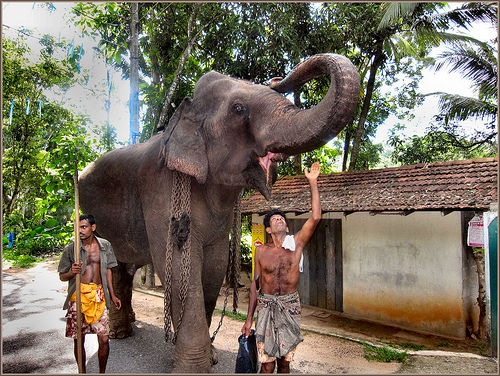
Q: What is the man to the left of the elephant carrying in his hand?
A: A bag.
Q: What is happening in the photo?
A: Two men are standing by an elephant.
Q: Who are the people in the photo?
A: Villagers.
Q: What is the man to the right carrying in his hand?
A: A stick.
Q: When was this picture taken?
A: During daylight.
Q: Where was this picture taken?
A: By the elephants.